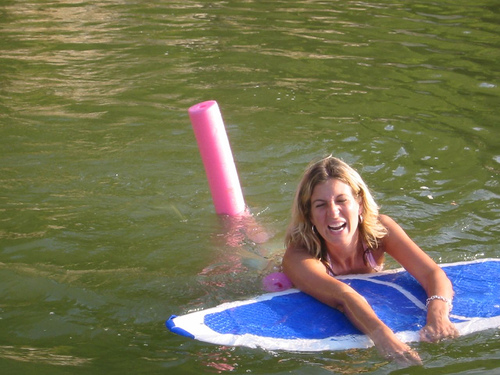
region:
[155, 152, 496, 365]
a woman on a surfboard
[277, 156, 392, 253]
a woman with blonde hair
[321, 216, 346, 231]
the teeth of a woman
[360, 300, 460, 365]
the hands of a woman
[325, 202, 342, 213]
the nose of a woman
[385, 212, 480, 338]
the arm of a woman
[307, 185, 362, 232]
the face of a woman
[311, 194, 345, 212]
the eyes of a woman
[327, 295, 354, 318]
the elbow of a woman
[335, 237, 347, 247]
the chin of a woman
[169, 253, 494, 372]
blue and white surf board in the water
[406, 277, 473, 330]
lady has arm band on left wrist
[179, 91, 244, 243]
pink pole in the water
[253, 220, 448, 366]
lady hanging on to surf board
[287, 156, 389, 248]
lady with her eyes closed in the water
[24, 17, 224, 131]
reflection off the green water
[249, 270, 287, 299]
pink flotation devise on surf board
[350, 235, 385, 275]
lady with pink bathing suit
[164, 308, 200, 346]
blue on the tip of the blue and white board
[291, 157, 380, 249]
woman with blond hair in the water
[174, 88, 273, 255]
pink foam pool toy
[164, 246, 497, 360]
blue and white surfboard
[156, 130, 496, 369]
woman hanging onto floating blue and white surfboard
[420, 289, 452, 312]
metal bracelet on woman's wrist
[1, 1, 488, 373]
green and brown water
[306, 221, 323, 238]
metal hoop earring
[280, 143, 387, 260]
shoulder length blonde hair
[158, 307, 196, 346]
blue plastic tip on surfboard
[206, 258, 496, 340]
textured blue surface in middle of surfboard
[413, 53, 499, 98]
dark ripple lines in water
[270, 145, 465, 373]
the woman in the water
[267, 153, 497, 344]
the woman is wet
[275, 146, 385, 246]
the woman is smiling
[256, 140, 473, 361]
the woman holding the surfboard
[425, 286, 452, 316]
the bracelet on the wrist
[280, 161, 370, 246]
the woman wearing earrings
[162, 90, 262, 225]
the tube in the water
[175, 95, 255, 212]
the tube is pink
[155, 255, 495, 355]
the surfboard is blue and white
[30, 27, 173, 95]
the water is calm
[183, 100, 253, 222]
A pool noodle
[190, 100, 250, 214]
A pink pool noodle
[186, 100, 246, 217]
A pink pool noodle sticking out of the water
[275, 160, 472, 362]
A young woman in the water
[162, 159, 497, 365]
A young woman grabbing a board in the water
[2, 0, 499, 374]
A young lady in a pool or murky green water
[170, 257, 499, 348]
A blue surfboard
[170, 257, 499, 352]
A blue surfboard with white trim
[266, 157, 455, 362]
I blond woman playing in the water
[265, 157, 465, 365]
A blond lady wearing a pink swimsuit